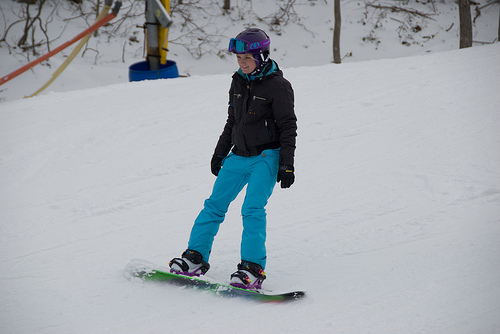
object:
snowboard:
[129, 257, 306, 303]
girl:
[168, 26, 298, 291]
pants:
[185, 147, 281, 271]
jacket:
[213, 57, 299, 165]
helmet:
[234, 28, 271, 57]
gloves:
[275, 163, 296, 189]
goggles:
[224, 37, 271, 54]